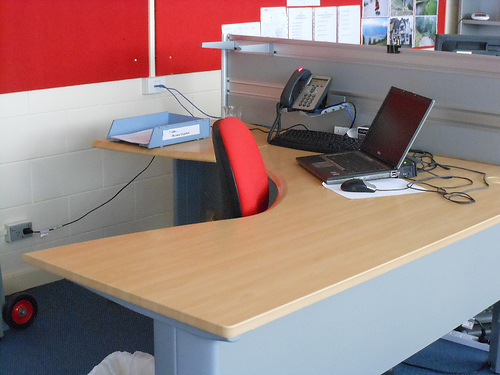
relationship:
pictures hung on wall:
[363, 0, 438, 47] [2, 1, 437, 46]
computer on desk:
[294, 86, 436, 185] [18, 112, 498, 373]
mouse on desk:
[342, 179, 375, 195] [37, 112, 499, 342]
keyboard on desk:
[321, 150, 387, 177] [37, 112, 499, 342]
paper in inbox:
[111, 129, 152, 146] [136, 76, 224, 158]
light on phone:
[296, 65, 306, 73] [262, 56, 341, 122]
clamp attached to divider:
[380, 40, 401, 68] [222, 30, 499, 165]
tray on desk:
[106, 110, 208, 151] [18, 112, 498, 373]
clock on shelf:
[471, 9, 491, 21] [458, 17, 499, 28]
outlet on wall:
[142, 76, 168, 94] [0, 2, 363, 296]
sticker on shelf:
[160, 121, 203, 141] [107, 110, 210, 150]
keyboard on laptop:
[321, 137, 376, 184] [298, 68, 446, 186]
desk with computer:
[18, 112, 498, 373] [294, 86, 436, 185]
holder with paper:
[99, 107, 217, 163] [110, 120, 175, 147]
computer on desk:
[294, 86, 436, 185] [20, 114, 450, 370]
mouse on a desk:
[340, 178, 375, 194] [18, 112, 498, 373]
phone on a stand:
[265, 64, 327, 121] [266, 104, 353, 151]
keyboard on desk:
[267, 126, 363, 154] [18, 112, 498, 373]